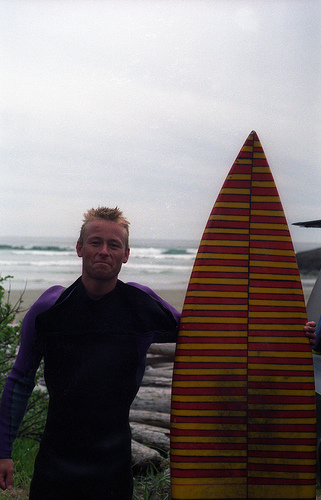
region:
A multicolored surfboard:
[185, 111, 309, 498]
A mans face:
[49, 169, 155, 279]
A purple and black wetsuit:
[3, 170, 141, 498]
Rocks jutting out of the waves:
[3, 233, 69, 258]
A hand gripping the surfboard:
[302, 306, 320, 349]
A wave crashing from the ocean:
[138, 239, 169, 290]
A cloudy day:
[24, 40, 183, 191]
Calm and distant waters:
[143, 238, 185, 249]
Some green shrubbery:
[0, 267, 45, 446]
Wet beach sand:
[2, 289, 41, 318]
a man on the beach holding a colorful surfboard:
[2, 183, 319, 498]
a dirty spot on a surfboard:
[212, 374, 289, 494]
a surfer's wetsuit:
[0, 273, 178, 491]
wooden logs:
[128, 353, 170, 462]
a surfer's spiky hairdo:
[86, 206, 129, 223]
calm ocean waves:
[2, 240, 192, 284]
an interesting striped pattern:
[194, 285, 302, 346]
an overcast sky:
[5, 4, 320, 131]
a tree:
[1, 275, 25, 370]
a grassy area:
[16, 440, 35, 482]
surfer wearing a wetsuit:
[3, 208, 180, 493]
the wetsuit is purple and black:
[2, 284, 178, 499]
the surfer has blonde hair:
[75, 203, 132, 285]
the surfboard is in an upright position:
[171, 130, 320, 499]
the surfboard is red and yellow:
[167, 128, 316, 498]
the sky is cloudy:
[0, 1, 320, 243]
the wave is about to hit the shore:
[2, 241, 199, 255]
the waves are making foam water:
[2, 247, 204, 269]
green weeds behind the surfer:
[1, 274, 50, 433]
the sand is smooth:
[3, 288, 318, 333]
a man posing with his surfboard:
[30, 128, 292, 492]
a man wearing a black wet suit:
[2, 199, 131, 484]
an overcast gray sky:
[110, 118, 191, 196]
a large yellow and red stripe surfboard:
[164, 126, 311, 495]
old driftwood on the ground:
[139, 380, 166, 452]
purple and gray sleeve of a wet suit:
[4, 284, 66, 445]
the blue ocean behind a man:
[26, 255, 68, 275]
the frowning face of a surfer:
[79, 203, 121, 281]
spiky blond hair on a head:
[76, 204, 130, 223]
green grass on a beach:
[15, 446, 23, 468]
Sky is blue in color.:
[24, 19, 109, 95]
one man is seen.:
[26, 180, 265, 422]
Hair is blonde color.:
[90, 202, 125, 222]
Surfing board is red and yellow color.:
[207, 256, 276, 409]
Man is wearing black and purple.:
[32, 299, 136, 423]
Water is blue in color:
[9, 251, 42, 267]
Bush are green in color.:
[2, 308, 13, 362]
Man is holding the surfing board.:
[169, 230, 308, 407]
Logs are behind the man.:
[139, 401, 164, 454]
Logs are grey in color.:
[144, 400, 166, 462]